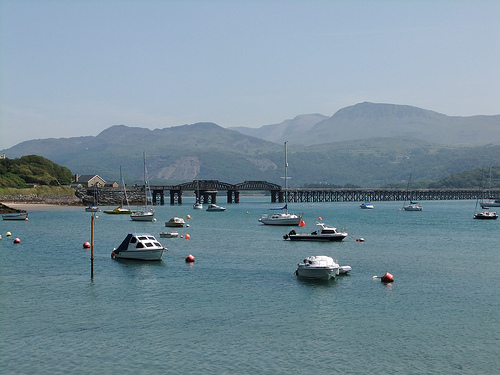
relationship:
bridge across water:
[76, 180, 500, 204] [2, 193, 500, 373]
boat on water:
[113, 232, 165, 263] [2, 193, 500, 373]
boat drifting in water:
[113, 232, 165, 263] [2, 193, 500, 373]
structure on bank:
[72, 173, 122, 191] [3, 181, 153, 209]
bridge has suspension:
[76, 180, 500, 204] [148, 180, 283, 207]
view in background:
[1, 3, 499, 198] [1, 2, 496, 193]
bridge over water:
[76, 180, 500, 204] [2, 193, 500, 373]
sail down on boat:
[279, 138, 294, 214] [258, 209, 302, 227]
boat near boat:
[113, 232, 165, 263] [160, 229, 183, 240]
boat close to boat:
[160, 229, 183, 240] [166, 216, 187, 227]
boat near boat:
[166, 216, 187, 227] [127, 207, 159, 222]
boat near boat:
[105, 205, 136, 216] [127, 207, 159, 222]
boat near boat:
[82, 205, 102, 214] [105, 205, 136, 216]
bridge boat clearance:
[76, 180, 500, 204] [173, 187, 279, 207]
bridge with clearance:
[76, 180, 500, 204] [173, 187, 279, 207]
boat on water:
[297, 253, 344, 281] [2, 193, 500, 373]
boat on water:
[284, 223, 350, 244] [2, 193, 500, 373]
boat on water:
[359, 201, 377, 211] [2, 193, 500, 373]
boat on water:
[400, 200, 424, 212] [2, 193, 500, 373]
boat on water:
[473, 211, 499, 220] [2, 193, 500, 373]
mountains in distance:
[1, 102, 499, 196] [1, 3, 499, 198]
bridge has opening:
[76, 180, 500, 204] [173, 187, 279, 207]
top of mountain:
[225, 112, 331, 146] [1, 102, 499, 196]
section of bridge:
[148, 180, 283, 207] [76, 180, 500, 204]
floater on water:
[374, 271, 395, 286] [2, 193, 500, 373]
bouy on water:
[182, 253, 198, 265] [2, 193, 500, 373]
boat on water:
[127, 207, 159, 222] [2, 193, 500, 373]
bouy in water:
[182, 253, 198, 265] [2, 193, 500, 373]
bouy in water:
[374, 271, 395, 286] [2, 193, 500, 373]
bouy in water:
[80, 239, 93, 253] [2, 193, 500, 373]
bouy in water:
[13, 235, 23, 246] [2, 193, 500, 373]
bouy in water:
[296, 219, 308, 229] [2, 193, 500, 373]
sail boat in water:
[116, 167, 131, 209] [2, 193, 500, 373]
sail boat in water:
[139, 145, 153, 213] [2, 193, 500, 373]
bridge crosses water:
[76, 180, 500, 204] [2, 193, 500, 373]